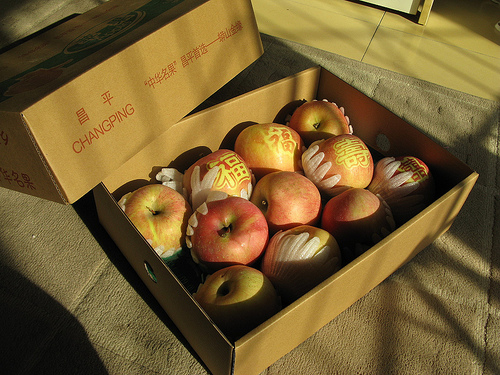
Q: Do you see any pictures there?
A: No, there are no pictures.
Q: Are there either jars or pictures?
A: No, there are no pictures or jars.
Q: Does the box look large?
A: Yes, the box is large.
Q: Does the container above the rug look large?
A: Yes, the box is large.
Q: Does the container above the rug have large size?
A: Yes, the box is large.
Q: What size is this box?
A: The box is large.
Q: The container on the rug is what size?
A: The box is large.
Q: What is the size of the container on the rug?
A: The box is large.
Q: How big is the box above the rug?
A: The box is large.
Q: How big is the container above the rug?
A: The box is large.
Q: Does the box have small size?
A: No, the box is large.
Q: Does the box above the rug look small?
A: No, the box is large.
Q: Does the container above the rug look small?
A: No, the box is large.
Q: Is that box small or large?
A: The box is large.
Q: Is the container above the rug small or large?
A: The box is large.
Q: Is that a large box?
A: Yes, that is a large box.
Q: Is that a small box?
A: No, that is a large box.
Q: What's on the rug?
A: The box is on the rug.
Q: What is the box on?
A: The box is on the rug.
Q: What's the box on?
A: The box is on the rug.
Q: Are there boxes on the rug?
A: Yes, there is a box on the rug.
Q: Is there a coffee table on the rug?
A: No, there is a box on the rug.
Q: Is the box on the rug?
A: Yes, the box is on the rug.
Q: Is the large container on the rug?
A: Yes, the box is on the rug.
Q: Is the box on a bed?
A: No, the box is on the rug.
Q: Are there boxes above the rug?
A: Yes, there is a box above the rug.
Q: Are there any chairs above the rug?
A: No, there is a box above the rug.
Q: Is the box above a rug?
A: Yes, the box is above a rug.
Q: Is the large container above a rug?
A: Yes, the box is above a rug.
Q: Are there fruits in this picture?
A: Yes, there is a fruit.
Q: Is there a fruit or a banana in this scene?
A: Yes, there is a fruit.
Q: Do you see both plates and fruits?
A: No, there is a fruit but no plates.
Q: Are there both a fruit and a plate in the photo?
A: No, there is a fruit but no plates.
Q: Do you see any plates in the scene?
A: No, there are no plates.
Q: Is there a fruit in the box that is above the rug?
A: Yes, there is a fruit in the box.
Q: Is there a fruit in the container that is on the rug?
A: Yes, there is a fruit in the box.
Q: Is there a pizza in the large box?
A: No, there is a fruit in the box.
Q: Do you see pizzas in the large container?
A: No, there is a fruit in the box.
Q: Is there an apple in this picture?
A: Yes, there is an apple.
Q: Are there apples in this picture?
A: Yes, there is an apple.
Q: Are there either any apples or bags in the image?
A: Yes, there is an apple.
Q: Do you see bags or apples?
A: Yes, there is an apple.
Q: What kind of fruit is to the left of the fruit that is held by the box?
A: The fruit is an apple.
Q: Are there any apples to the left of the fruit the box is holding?
A: Yes, there is an apple to the left of the fruit.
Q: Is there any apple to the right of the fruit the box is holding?
A: No, the apple is to the left of the fruit.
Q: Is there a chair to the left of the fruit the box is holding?
A: No, there is an apple to the left of the fruit.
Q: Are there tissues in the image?
A: No, there are no tissues.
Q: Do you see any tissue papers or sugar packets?
A: No, there are no tissue papers or sugar packets.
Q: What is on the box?
A: The lid is on the box.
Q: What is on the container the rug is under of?
A: The lid is on the box.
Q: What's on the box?
A: The lid is on the box.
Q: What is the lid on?
A: The lid is on the box.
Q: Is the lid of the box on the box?
A: Yes, the lid is on the box.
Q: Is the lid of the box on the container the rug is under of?
A: Yes, the lid is on the box.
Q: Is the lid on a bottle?
A: No, the lid is on the box.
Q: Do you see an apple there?
A: Yes, there are apples.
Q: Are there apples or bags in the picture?
A: Yes, there are apples.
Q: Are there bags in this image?
A: No, there are no bags.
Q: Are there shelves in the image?
A: No, there are no shelves.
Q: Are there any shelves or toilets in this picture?
A: No, there are no shelves or toilets.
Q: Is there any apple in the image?
A: Yes, there is an apple.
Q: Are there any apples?
A: Yes, there is an apple.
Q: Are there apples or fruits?
A: Yes, there is an apple.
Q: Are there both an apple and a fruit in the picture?
A: Yes, there are both an apple and a fruit.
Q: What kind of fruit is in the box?
A: The fruit is an apple.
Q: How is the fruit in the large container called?
A: The fruit is an apple.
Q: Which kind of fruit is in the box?
A: The fruit is an apple.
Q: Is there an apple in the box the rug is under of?
A: Yes, there is an apple in the box.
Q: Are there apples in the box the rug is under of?
A: Yes, there is an apple in the box.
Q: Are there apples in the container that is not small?
A: Yes, there is an apple in the box.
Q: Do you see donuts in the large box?
A: No, there is an apple in the box.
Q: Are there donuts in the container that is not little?
A: No, there is an apple in the box.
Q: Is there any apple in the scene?
A: Yes, there is an apple.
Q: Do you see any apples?
A: Yes, there is an apple.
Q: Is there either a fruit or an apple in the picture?
A: Yes, there is an apple.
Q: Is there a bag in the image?
A: No, there are no bags.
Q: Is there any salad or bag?
A: No, there are no bags or salad.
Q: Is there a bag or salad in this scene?
A: No, there are no bags or salad.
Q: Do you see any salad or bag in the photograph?
A: No, there are no bags or salad.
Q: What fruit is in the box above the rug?
A: The fruit is an apple.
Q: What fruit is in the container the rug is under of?
A: The fruit is an apple.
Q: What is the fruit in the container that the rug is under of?
A: The fruit is an apple.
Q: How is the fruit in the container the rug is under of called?
A: The fruit is an apple.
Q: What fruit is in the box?
A: The fruit is an apple.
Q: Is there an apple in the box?
A: Yes, there is an apple in the box.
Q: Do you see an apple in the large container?
A: Yes, there is an apple in the box.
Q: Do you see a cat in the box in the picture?
A: No, there is an apple in the box.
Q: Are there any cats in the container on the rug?
A: No, there is an apple in the box.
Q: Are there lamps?
A: No, there are no lamps.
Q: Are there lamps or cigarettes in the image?
A: No, there are no lamps or cigarettes.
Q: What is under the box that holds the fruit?
A: The rug is under the box.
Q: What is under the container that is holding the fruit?
A: The rug is under the box.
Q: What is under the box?
A: The rug is under the box.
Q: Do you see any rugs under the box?
A: Yes, there is a rug under the box.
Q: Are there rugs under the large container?
A: Yes, there is a rug under the box.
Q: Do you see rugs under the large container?
A: Yes, there is a rug under the box.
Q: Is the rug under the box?
A: Yes, the rug is under the box.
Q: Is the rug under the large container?
A: Yes, the rug is under the box.